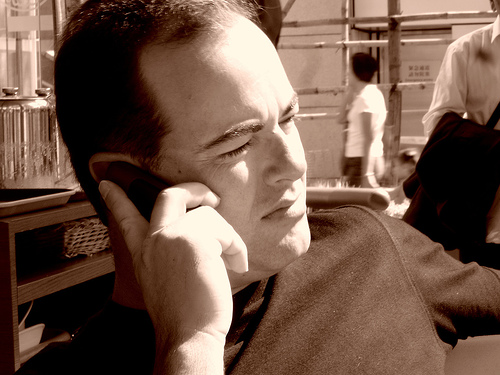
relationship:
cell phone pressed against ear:
[102, 159, 203, 225] [88, 152, 150, 187]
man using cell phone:
[9, 1, 499, 374] [102, 159, 203, 225]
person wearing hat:
[341, 51, 389, 188] [350, 52, 379, 83]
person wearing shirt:
[403, 0, 500, 269] [422, 11, 500, 246]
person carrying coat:
[403, 0, 500, 269] [402, 110, 500, 266]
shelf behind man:
[0, 198, 116, 374] [9, 1, 499, 374]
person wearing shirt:
[341, 51, 389, 188] [344, 83, 388, 158]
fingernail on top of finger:
[98, 179, 111, 199] [97, 179, 150, 253]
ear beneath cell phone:
[88, 152, 150, 187] [102, 159, 203, 225]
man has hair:
[9, 1, 499, 374] [53, 0, 280, 230]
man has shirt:
[9, 1, 499, 374] [13, 203, 500, 374]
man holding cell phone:
[9, 1, 499, 374] [102, 159, 203, 225]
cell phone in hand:
[102, 159, 203, 225] [98, 178, 250, 339]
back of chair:
[14, 340, 72, 374] [13, 339, 69, 374]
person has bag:
[403, 0, 500, 269] [485, 97, 500, 129]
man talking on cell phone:
[9, 1, 499, 374] [102, 159, 203, 225]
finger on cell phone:
[97, 179, 150, 253] [102, 159, 203, 225]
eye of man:
[216, 134, 253, 165] [9, 1, 499, 374]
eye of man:
[280, 108, 301, 129] [9, 1, 499, 374]